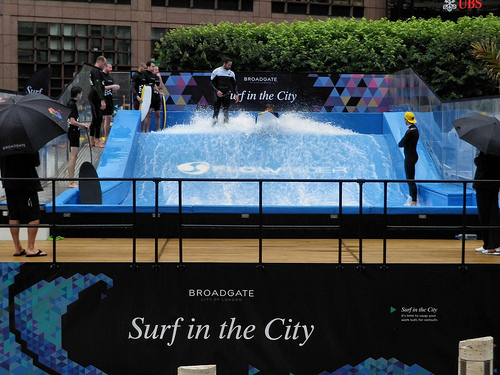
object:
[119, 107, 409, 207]
water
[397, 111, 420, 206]
person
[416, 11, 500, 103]
bush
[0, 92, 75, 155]
umbrella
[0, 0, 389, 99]
building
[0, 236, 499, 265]
floor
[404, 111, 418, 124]
cap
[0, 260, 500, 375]
banner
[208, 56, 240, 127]
person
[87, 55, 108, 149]
person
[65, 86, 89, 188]
person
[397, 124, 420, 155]
top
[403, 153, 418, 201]
pants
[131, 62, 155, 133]
person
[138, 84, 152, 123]
object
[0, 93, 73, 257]
person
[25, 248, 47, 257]
sandal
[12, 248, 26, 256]
sandal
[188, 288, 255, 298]
word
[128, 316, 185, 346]
word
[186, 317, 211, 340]
word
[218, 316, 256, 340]
word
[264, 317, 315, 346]
word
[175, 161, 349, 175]
logo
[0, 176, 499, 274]
rail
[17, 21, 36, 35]
window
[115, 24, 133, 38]
window